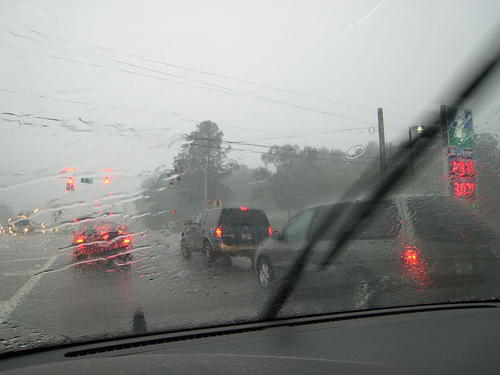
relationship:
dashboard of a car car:
[2, 297, 499, 373] [63, 212, 132, 269]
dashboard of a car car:
[2, 297, 499, 373] [174, 204, 271, 263]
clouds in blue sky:
[0, 0, 500, 228] [347, 100, 394, 115]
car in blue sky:
[71, 220, 134, 275] [347, 100, 394, 115]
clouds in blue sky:
[0, 0, 500, 228] [60, 59, 117, 114]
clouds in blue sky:
[0, 0, 500, 228] [84, 50, 125, 99]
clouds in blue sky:
[68, 54, 110, 119] [4, 2, 494, 190]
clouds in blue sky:
[0, 0, 500, 228] [4, 2, 496, 104]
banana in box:
[159, 199, 425, 283] [264, 132, 439, 301]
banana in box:
[255, 193, 500, 309] [229, 110, 444, 296]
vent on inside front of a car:
[65, 296, 498, 364] [0, 0, 500, 374]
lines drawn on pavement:
[0, 254, 57, 326] [108, 267, 213, 319]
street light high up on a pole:
[409, 122, 424, 134] [406, 126, 416, 188]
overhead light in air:
[54, 162, 78, 193] [64, 143, 115, 170]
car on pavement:
[254, 195, 500, 310] [0, 229, 500, 342]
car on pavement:
[71, 220, 134, 275] [0, 229, 500, 342]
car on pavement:
[179, 205, 272, 271] [0, 229, 500, 342]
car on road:
[74, 220, 134, 263] [0, 245, 272, 353]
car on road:
[179, 205, 272, 271] [0, 245, 272, 353]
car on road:
[254, 195, 500, 310] [0, 245, 272, 353]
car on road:
[0, 28, 496, 373] [0, 245, 272, 353]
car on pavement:
[3, 215, 31, 237] [0, 229, 500, 342]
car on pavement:
[248, 197, 496, 310] [0, 229, 500, 342]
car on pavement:
[0, 28, 496, 373] [0, 229, 500, 342]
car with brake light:
[254, 195, 500, 310] [399, 245, 420, 267]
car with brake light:
[174, 200, 275, 263] [209, 224, 221, 236]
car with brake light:
[174, 200, 275, 263] [267, 222, 277, 236]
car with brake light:
[71, 220, 134, 275] [120, 233, 131, 250]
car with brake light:
[71, 220, 134, 275] [77, 235, 84, 247]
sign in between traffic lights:
[80, 176, 94, 185] [55, 165, 123, 192]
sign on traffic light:
[80, 178, 93, 185] [61, 165, 112, 190]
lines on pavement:
[0, 251, 62, 326] [0, 229, 500, 342]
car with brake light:
[179, 205, 272, 271] [77, 239, 84, 243]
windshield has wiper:
[0, 1, 497, 361] [263, 56, 500, 319]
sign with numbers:
[447, 161, 479, 198] [449, 154, 475, 204]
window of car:
[215, 207, 270, 225] [179, 205, 272, 271]